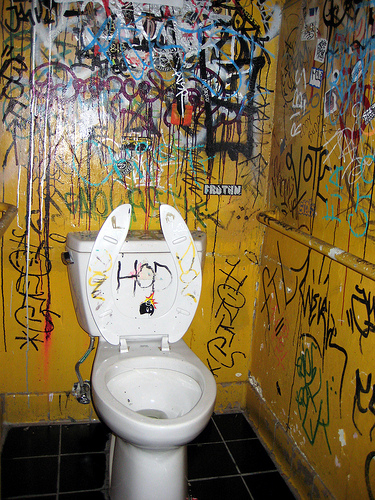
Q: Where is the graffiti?
A: Walls.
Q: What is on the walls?
A: Graffiti.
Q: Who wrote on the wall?
A: Graffitist.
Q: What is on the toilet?
A: Germs.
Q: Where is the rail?
A: Beside the toilet.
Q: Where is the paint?
A: On the toilet.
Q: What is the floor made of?
A: Black tile.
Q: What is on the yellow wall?
A: Graffiti.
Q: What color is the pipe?
A: Yellow.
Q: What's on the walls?
A: Graffiti.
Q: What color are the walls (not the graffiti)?
A: Yellow.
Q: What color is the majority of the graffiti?
A: Black.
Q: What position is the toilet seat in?
A: Raised.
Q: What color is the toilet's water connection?
A: Silver.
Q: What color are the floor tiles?
A: Black.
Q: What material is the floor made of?
A: Tile.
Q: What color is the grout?
A: Gray.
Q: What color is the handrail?
A: Yellow.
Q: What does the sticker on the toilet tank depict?
A: Bomb.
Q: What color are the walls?
A: Yellow.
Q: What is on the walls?
A: Graffiti.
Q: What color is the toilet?
A: White.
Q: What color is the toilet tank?
A: White.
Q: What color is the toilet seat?
A: White.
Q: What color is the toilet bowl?
A: White.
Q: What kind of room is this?
A: Bathroom.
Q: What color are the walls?
A: Yellow.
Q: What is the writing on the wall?
A: Graffiti.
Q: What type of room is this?
A: A bathroom.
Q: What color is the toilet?
A: White.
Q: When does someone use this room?
A: When they need to use the toilet.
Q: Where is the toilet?
A: In a bathroom.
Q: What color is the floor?
A: Black.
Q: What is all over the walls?
A: Graffiti.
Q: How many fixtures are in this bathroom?
A: One.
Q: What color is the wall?
A: Yellow.